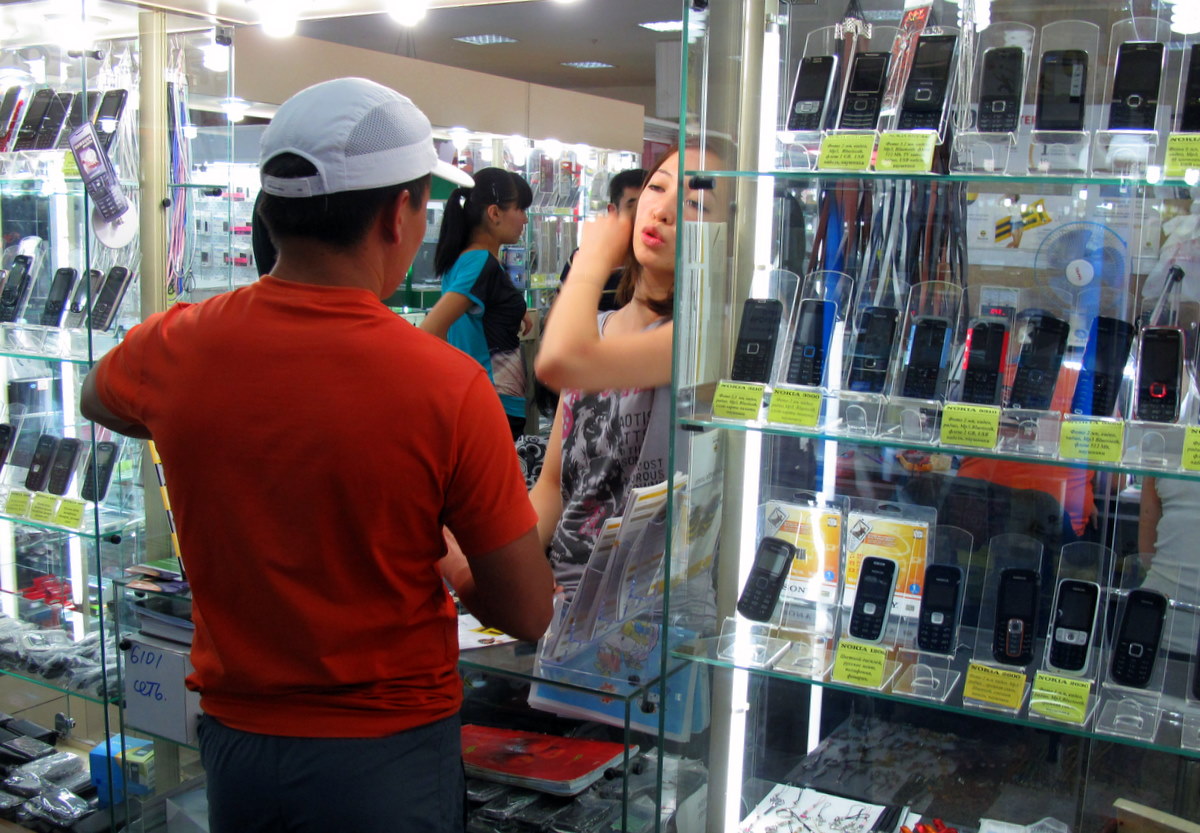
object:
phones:
[918, 563, 968, 657]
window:
[172, 0, 726, 646]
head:
[253, 156, 430, 297]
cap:
[258, 78, 474, 198]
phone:
[729, 299, 783, 386]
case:
[631, 0, 1200, 833]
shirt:
[89, 276, 545, 742]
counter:
[105, 555, 703, 833]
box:
[127, 631, 205, 748]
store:
[0, 0, 1198, 833]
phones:
[1004, 315, 1069, 410]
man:
[81, 74, 554, 833]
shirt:
[441, 249, 531, 419]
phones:
[1111, 590, 1166, 690]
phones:
[1137, 329, 1185, 426]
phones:
[977, 46, 1023, 133]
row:
[781, 35, 1200, 135]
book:
[458, 723, 641, 797]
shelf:
[467, 709, 705, 833]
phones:
[847, 556, 901, 644]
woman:
[522, 145, 747, 665]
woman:
[414, 165, 536, 447]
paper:
[713, 379, 767, 423]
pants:
[190, 713, 467, 833]